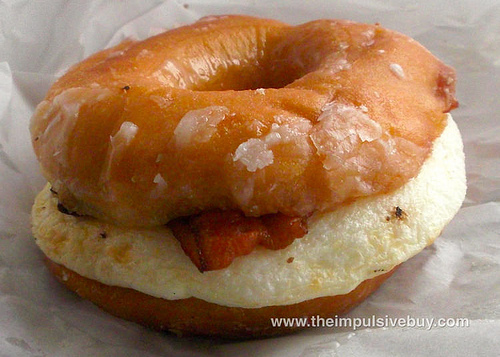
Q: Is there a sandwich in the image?
A: Yes, there is a sandwich.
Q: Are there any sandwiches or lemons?
A: Yes, there is a sandwich.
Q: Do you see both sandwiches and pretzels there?
A: No, there is a sandwich but no pretzels.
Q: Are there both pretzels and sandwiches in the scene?
A: No, there is a sandwich but no pretzels.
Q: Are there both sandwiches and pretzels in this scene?
A: No, there is a sandwich but no pretzels.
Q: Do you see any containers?
A: No, there are no containers.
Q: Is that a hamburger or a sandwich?
A: That is a sandwich.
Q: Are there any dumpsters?
A: No, there are no dumpsters.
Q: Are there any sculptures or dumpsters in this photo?
A: No, there are no dumpsters or sculptures.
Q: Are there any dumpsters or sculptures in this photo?
A: No, there are no dumpsters or sculptures.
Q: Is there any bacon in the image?
A: Yes, there is bacon.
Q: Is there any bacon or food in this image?
A: Yes, there is bacon.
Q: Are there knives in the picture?
A: No, there are no knives.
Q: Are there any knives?
A: No, there are no knives.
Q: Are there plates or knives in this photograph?
A: No, there are no knives or plates.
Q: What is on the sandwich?
A: The bacon is on the sandwich.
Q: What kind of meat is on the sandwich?
A: The meat is bacon.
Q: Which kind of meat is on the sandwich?
A: The meat is bacon.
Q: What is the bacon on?
A: The bacon is on the sandwich.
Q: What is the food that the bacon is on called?
A: The food is a sandwich.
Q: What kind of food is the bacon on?
A: The bacon is on the sandwich.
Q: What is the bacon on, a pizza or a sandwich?
A: The bacon is on a sandwich.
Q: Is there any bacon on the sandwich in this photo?
A: Yes, there is bacon on the sandwich.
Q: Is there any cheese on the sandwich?
A: No, there is bacon on the sandwich.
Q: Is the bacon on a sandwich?
A: Yes, the bacon is on a sandwich.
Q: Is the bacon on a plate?
A: No, the bacon is on a sandwich.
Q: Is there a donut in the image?
A: Yes, there is a donut.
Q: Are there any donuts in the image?
A: Yes, there is a donut.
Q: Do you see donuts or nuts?
A: Yes, there is a donut.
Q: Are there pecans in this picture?
A: No, there are no pecans.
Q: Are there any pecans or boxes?
A: No, there are no pecans or boxes.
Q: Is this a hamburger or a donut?
A: This is a donut.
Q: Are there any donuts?
A: Yes, there is a donut.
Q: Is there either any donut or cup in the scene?
A: Yes, there is a donut.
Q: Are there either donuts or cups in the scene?
A: Yes, there is a donut.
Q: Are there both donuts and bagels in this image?
A: No, there is a donut but no bagels.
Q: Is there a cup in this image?
A: No, there are no cups.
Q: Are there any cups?
A: No, there are no cups.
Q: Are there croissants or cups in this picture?
A: No, there are no cups or croissants.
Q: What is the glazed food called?
A: The food is a donut.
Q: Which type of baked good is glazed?
A: The baked good is a donut.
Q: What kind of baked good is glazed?
A: The baked good is a donut.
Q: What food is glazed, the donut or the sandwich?
A: The donut is glazed.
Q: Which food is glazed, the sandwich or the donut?
A: The donut is glazed.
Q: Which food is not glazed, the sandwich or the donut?
A: The sandwich is not glazed.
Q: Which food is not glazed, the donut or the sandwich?
A: The sandwich is not glazed.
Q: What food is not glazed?
A: The food is a sandwich.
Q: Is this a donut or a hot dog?
A: This is a donut.